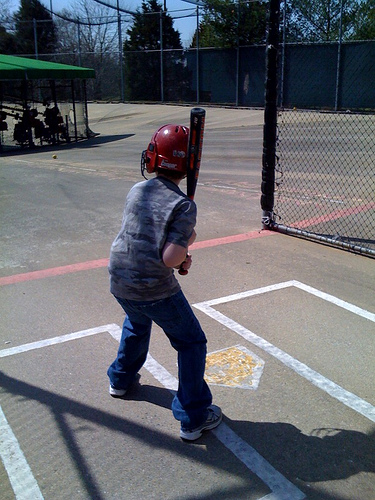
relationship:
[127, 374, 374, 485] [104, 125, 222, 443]
shadow of boy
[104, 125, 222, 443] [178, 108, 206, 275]
boy holding bat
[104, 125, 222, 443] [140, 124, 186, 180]
boy wearing a helmet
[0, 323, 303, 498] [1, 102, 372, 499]
lines on ground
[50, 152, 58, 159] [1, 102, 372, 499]
ball on ground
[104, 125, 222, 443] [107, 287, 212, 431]
boy wearing jeans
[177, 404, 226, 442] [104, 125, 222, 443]
shoe on boy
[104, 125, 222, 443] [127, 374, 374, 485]
boy has a shadow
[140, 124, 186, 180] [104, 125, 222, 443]
helmet of boy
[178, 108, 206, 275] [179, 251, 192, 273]
bat in hand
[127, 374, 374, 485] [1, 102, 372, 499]
shadow falls on ground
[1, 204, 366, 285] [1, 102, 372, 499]
line marked on ground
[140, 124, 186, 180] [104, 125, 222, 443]
helmet on boy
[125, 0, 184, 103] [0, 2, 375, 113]
tree behind fence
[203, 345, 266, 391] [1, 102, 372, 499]
home base plate on ground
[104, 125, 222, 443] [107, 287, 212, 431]
boy wearing a pair of jeans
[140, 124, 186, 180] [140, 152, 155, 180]
helmet has a mask